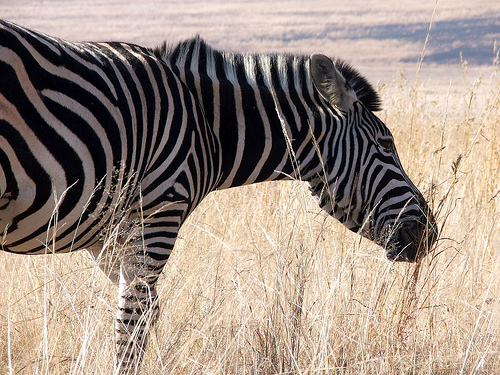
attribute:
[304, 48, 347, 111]
ear — zebras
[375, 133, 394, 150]
eye — Zebras, black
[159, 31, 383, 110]
mane — black and white, zebra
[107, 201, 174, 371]
leg — zebras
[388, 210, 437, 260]
snout — black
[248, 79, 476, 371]
grass — tall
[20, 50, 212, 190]
pattern — striped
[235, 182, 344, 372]
grass — tall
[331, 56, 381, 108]
hair — black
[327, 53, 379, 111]
mane — short, spiky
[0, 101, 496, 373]
grass — tall, brown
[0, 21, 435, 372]
zebra — black and white, brown, black, white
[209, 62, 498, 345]
grass — tall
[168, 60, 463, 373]
grass — tall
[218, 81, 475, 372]
grass — tall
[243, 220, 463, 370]
food — dry grass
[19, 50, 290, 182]
stripes — perfect, black, white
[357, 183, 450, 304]
nose — black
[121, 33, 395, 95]
mae — black, white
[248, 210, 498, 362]
grass — long, brown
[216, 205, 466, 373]
grass — brown, wiry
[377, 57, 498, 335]
grass — long, stalky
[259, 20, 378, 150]
ears — white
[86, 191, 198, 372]
stripes — small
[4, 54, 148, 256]
stripes — large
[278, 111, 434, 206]
stripes — thin